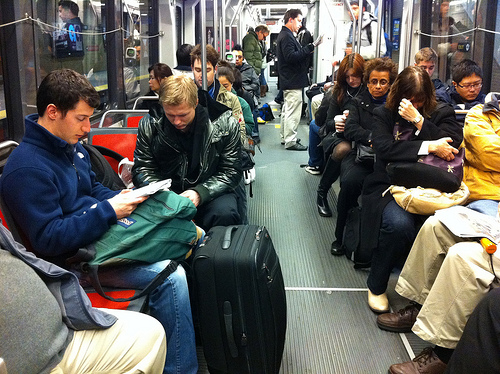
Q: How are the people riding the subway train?
A: Standing and sitting.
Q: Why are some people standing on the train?
A: No seats available.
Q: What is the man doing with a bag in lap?
A: Reading.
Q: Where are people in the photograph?
A: Subway train.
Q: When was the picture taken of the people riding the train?
A: Evening.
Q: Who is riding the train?
A: Men and women.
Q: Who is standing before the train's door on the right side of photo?
A: A man.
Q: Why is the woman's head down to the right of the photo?
A: Fatigue.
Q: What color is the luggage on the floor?
A: Black.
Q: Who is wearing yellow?
A: Person on right.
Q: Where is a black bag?
A: On the floor.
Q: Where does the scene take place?
A: In a train.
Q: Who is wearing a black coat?
A: Man standing.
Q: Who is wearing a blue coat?
A: Guy on left.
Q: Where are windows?
A: On the sides of the train.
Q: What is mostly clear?
A: The aisle.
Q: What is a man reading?
A: Papers.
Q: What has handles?
A: A black bag.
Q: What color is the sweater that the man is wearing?
A: It is blue.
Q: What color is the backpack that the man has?
A: Green.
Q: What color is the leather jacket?
A: It is black.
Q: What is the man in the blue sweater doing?
A: Reading a book.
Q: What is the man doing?
A: Reading.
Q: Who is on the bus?
A: Commuters.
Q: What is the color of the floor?
A: Grey.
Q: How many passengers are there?
A: 34.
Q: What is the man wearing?
A: Khakis.